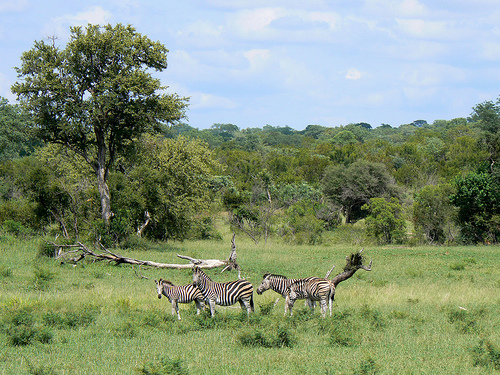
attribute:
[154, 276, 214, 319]
zebra — black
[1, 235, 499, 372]
field — yellow, green, grassy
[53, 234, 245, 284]
tree — fallen, dead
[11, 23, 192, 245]
tree — tall, green, large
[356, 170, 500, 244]
foliage — lush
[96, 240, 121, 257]
branch — fallen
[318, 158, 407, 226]
tree — small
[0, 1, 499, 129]
sky — blue, cloudy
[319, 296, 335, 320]
legs — thin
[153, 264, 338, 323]
zebras — black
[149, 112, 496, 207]
hills — green